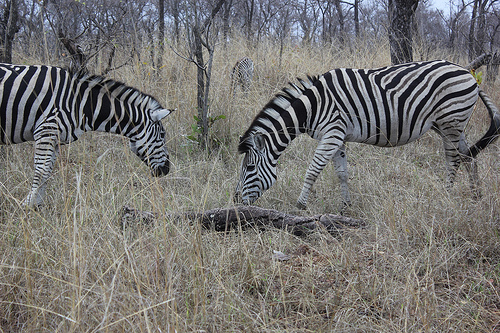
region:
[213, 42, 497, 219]
This is a zebra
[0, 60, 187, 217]
This is a zebra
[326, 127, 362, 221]
This is a leg of zebra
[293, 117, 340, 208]
This is a leg of zebra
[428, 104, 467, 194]
This is a leg of zebra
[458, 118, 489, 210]
This is a leg of zebra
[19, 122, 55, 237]
This is a leg of zebra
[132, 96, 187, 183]
This is a head of zebra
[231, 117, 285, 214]
This is a head of zebra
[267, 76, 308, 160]
This is a neck of zebra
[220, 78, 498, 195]
The zebra is standing.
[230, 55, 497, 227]
The zebra is black and white.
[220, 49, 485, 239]
The zebra is eating.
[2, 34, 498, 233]
The zebras are standing.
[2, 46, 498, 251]
The zebras are grazing.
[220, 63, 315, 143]
The mane is black and white.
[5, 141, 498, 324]
The grass is dead.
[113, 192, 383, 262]
The trunk is on the ground.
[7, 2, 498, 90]
The trees are bare.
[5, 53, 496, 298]
two zebras in the grass.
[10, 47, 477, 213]
3 zebras in the wild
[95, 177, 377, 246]
a dead animal in the grass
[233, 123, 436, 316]
the grass is high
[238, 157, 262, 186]
the eye is black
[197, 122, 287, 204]
the zebra is smelling the animal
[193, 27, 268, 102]
a zebra in the background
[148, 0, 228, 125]
the trees are bare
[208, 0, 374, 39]
see the sky through the trees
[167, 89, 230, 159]
green leaves growing in the grass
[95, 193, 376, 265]
the animal has grey brownish fur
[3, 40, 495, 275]
two zebras in the grass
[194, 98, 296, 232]
head bent down towards the ground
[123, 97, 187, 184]
head slightly bent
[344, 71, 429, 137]
black and white stripes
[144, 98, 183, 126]
pointy white ear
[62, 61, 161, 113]
hair along the neck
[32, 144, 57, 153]
thin black line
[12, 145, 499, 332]
long, yellowish grass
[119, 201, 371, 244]
something laying on the ground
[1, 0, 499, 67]
several trees growing in the long grass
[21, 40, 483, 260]
three zebras in the grass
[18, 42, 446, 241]
zebras in a field of grass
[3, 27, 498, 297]
the zebras are striped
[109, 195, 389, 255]
the log on the grass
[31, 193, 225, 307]
the grass is tall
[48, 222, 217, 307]
the grass is dry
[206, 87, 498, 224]
the zebra eating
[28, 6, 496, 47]
the trees with no leaves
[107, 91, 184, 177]
the head of a zebra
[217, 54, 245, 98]
the tail of a zebra